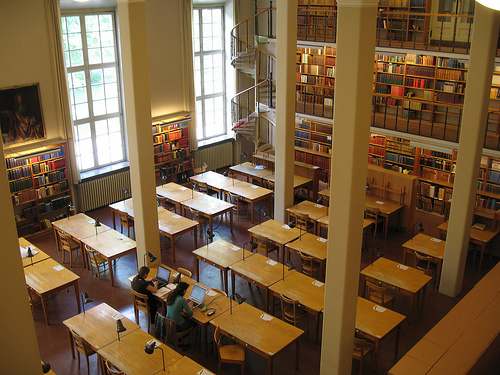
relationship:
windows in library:
[55, 6, 143, 193] [8, 12, 455, 373]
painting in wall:
[0, 86, 55, 146] [2, 2, 67, 137]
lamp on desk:
[114, 317, 126, 344] [94, 327, 183, 374]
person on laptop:
[132, 259, 163, 322] [149, 262, 169, 291]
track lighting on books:
[150, 105, 188, 115] [12, 158, 66, 171]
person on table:
[133, 266, 162, 309] [129, 261, 237, 323]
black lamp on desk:
[91, 217, 101, 236] [51, 212, 137, 287]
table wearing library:
[182, 228, 409, 360] [3, 0, 498, 373]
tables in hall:
[51, 176, 415, 337] [3, 0, 498, 368]